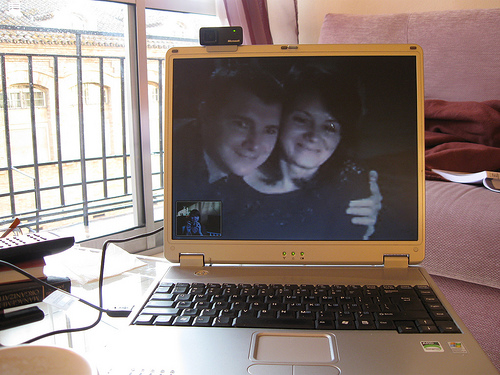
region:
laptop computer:
[98, 25, 498, 371]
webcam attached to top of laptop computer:
[198, 23, 243, 46]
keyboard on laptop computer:
[129, 280, 462, 335]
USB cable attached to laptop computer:
[0, 258, 135, 317]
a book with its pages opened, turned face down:
[431, 168, 498, 194]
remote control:
[0, 232, 73, 263]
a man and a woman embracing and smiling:
[174, 59, 384, 239]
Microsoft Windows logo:
[446, 340, 468, 355]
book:
[0, 275, 70, 310]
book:
[0, 257, 48, 287]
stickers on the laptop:
[405, 332, 472, 359]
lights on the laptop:
[274, 245, 314, 260]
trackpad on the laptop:
[240, 324, 335, 366]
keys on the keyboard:
[188, 286, 414, 328]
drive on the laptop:
[101, 304, 135, 319]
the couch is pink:
[444, 230, 483, 265]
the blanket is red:
[452, 112, 484, 143]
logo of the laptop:
[270, 43, 300, 53]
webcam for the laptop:
[197, 27, 247, 43]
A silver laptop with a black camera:
[107, 27, 497, 373]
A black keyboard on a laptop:
[134, 281, 462, 335]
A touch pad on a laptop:
[254, 333, 332, 363]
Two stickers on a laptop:
[421, 338, 466, 355]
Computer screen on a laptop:
[170, 58, 418, 240]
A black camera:
[198, 26, 243, 50]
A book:
[434, 167, 498, 193]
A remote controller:
[0, 227, 77, 262]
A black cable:
[1, 228, 163, 347]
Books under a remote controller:
[1, 258, 71, 306]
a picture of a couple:
[188, 79, 398, 234]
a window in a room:
[0, 2, 138, 237]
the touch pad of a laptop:
[250, 329, 342, 364]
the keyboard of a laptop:
[135, 278, 459, 337]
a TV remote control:
[0, 225, 77, 260]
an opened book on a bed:
[428, 160, 498, 190]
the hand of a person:
[345, 166, 389, 242]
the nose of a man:
[243, 133, 267, 158]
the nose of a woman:
[302, 126, 328, 147]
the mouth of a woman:
[292, 138, 327, 158]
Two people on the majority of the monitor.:
[187, 74, 415, 196]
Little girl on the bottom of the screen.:
[167, 188, 220, 245]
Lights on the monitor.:
[274, 249, 314, 263]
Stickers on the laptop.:
[406, 334, 470, 360]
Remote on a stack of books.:
[0, 221, 85, 264]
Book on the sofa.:
[412, 158, 499, 192]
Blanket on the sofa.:
[411, 101, 499, 168]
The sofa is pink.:
[424, 192, 489, 257]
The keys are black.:
[128, 281, 462, 335]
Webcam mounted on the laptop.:
[181, 23, 255, 55]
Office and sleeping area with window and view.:
[0, 10, 498, 369]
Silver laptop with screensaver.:
[170, 57, 427, 370]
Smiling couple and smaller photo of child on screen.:
[177, 69, 419, 236]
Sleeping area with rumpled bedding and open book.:
[426, 77, 497, 204]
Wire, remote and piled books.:
[1, 215, 93, 345]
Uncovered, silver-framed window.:
[5, 12, 155, 247]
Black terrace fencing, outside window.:
[3, 58, 133, 225]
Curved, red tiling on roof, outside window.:
[6, 30, 123, 47]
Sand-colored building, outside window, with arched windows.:
[5, 41, 127, 203]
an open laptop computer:
[97, 42, 497, 374]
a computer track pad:
[251, 333, 333, 362]